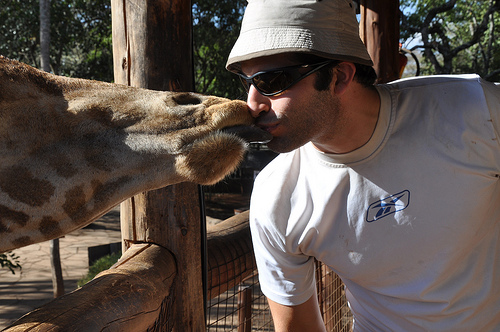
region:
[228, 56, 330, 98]
black sunglasses on man's face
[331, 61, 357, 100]
the man's left ear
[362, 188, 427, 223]
blue reebok sign on shirt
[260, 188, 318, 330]
the man's right arm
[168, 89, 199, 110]
right nostril of giraffe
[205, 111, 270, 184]
mouth of the giraffe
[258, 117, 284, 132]
mouth of the man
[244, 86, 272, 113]
the nose on the man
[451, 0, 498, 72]
branch on the tree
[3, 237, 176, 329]
wooden fence in front of giraffe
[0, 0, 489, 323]
man kissing the giraffe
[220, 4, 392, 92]
man wearing a hat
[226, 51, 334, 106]
man is wearing sun glasses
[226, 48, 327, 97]
the sun glasses are black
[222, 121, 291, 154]
giraffe's tongue touching man's lips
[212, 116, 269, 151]
giraffe's tongue is purple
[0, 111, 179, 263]
giraffe has spots on it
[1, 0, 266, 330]
wooden post beside giraffe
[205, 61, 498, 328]
man's shirt is white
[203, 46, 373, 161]
a man wearing black sunglasses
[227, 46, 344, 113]
a man wearing sunglasses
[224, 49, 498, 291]
a man wearing a white shirt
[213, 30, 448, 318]
a man wearing a tshirt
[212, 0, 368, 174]
a man wearing a tan hat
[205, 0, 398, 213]
a man wearing a hat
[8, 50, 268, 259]
a brown and tan giraffe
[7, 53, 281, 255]
a tan and brown giraffe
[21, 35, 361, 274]
a giraffe licking a man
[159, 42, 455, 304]
a man getting licked by a giraffe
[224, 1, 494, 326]
man with a tan hat and sunglasses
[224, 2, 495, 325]
man with white tee shirt with a black logo on the front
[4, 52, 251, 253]
head of a giraffe giving a man a sniff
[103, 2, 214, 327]
brown wooden post of a brown fence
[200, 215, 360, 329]
black metal mesh on a wooden fence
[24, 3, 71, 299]
skinny tree in a giraffe pen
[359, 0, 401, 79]
wooden post to a wooden fence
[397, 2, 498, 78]
green tree with curved branches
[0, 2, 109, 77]
green foliage behind the giraffe's head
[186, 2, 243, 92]
green foliage with some blue sky showing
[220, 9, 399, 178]
the head of a man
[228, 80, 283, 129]
the nose of a man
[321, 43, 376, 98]
the ear of a man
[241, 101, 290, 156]
the lips of a man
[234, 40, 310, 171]
the face of a man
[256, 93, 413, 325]
the arm of a man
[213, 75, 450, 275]
a man wearing a shirt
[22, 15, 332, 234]
the mouth of a giraffe